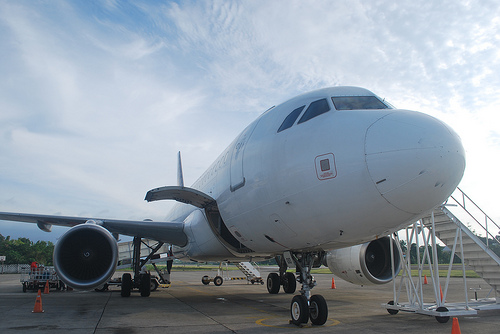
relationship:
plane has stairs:
[3, 52, 469, 323] [428, 182, 499, 309]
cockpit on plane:
[276, 93, 391, 134] [3, 52, 469, 323]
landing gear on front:
[283, 242, 330, 332] [263, 72, 486, 332]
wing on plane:
[0, 200, 188, 253] [3, 52, 469, 323]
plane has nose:
[3, 52, 469, 323] [352, 102, 477, 226]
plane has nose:
[3, 52, 469, 323] [373, 103, 469, 220]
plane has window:
[3, 52, 469, 323] [323, 88, 388, 120]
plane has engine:
[3, 52, 469, 323] [50, 222, 125, 292]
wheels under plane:
[285, 287, 343, 324] [59, 99, 472, 304]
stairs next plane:
[397, 125, 498, 309] [173, 36, 495, 310]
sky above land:
[2, 3, 492, 123] [42, 294, 262, 332]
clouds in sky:
[11, 17, 206, 121] [0, 0, 500, 82]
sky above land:
[2, 3, 492, 123] [4, 268, 495, 332]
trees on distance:
[357, 261, 467, 321] [9, 243, 498, 273]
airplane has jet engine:
[2, 83, 467, 324] [324, 235, 406, 282]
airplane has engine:
[2, 83, 467, 324] [52, 222, 121, 290]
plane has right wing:
[3, 52, 469, 323] [0, 209, 187, 249]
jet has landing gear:
[0, 81, 467, 329] [283, 242, 330, 332]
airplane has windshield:
[2, 83, 467, 324] [275, 85, 465, 182]